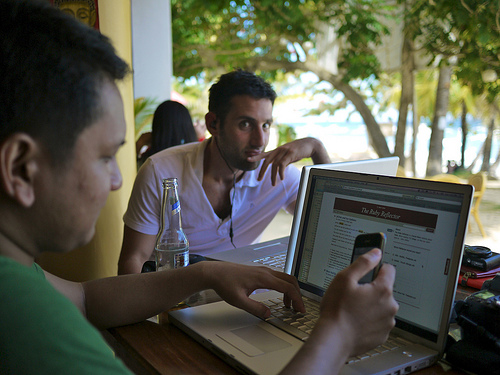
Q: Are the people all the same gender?
A: No, they are both male and female.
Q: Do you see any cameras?
A: Yes, there is a camera.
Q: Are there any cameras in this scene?
A: Yes, there is a camera.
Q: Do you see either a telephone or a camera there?
A: Yes, there is a camera.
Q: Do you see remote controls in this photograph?
A: No, there are no remote controls.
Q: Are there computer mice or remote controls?
A: No, there are no remote controls or computer mice.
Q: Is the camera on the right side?
A: Yes, the camera is on the right of the image.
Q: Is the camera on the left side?
A: No, the camera is on the right of the image.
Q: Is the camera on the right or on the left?
A: The camera is on the right of the image.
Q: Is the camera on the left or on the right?
A: The camera is on the right of the image.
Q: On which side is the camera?
A: The camera is on the right of the image.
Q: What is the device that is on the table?
A: The device is a camera.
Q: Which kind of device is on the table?
A: The device is a camera.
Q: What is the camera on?
A: The camera is on the table.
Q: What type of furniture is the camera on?
A: The camera is on the table.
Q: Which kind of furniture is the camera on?
A: The camera is on the table.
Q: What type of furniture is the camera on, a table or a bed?
A: The camera is on a table.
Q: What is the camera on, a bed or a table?
A: The camera is on a table.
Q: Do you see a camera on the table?
A: Yes, there is a camera on the table.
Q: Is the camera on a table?
A: Yes, the camera is on a table.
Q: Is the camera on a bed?
A: No, the camera is on a table.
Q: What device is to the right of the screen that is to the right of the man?
A: The device is a camera.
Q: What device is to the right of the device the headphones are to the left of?
A: The device is a camera.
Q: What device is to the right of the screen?
A: The device is a camera.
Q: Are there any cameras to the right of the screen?
A: Yes, there is a camera to the right of the screen.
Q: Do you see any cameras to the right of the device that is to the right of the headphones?
A: Yes, there is a camera to the right of the screen.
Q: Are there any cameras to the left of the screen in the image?
A: No, the camera is to the right of the screen.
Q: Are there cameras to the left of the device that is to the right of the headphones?
A: No, the camera is to the right of the screen.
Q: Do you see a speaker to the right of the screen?
A: No, there is a camera to the right of the screen.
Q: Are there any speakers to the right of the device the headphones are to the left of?
A: No, there is a camera to the right of the screen.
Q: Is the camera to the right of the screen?
A: Yes, the camera is to the right of the screen.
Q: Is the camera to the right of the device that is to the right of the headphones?
A: Yes, the camera is to the right of the screen.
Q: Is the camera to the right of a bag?
A: No, the camera is to the right of the screen.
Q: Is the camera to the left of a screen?
A: No, the camera is to the right of a screen.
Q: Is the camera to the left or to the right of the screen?
A: The camera is to the right of the screen.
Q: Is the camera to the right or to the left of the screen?
A: The camera is to the right of the screen.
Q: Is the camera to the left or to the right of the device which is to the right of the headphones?
A: The camera is to the right of the screen.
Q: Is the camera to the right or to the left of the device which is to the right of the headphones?
A: The camera is to the right of the screen.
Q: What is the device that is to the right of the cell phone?
A: The device is a camera.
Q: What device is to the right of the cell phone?
A: The device is a camera.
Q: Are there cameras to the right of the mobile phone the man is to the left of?
A: Yes, there is a camera to the right of the mobile phone.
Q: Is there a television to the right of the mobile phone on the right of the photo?
A: No, there is a camera to the right of the cell phone.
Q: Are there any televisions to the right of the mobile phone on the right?
A: No, there is a camera to the right of the cell phone.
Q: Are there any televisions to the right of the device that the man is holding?
A: No, there is a camera to the right of the cell phone.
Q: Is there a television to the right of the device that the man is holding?
A: No, there is a camera to the right of the cell phone.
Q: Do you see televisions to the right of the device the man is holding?
A: No, there is a camera to the right of the cell phone.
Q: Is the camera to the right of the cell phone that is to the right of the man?
A: Yes, the camera is to the right of the mobile phone.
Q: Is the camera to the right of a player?
A: No, the camera is to the right of the mobile phone.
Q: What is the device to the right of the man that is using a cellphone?
A: The device is a camera.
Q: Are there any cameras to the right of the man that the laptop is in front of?
A: Yes, there is a camera to the right of the man.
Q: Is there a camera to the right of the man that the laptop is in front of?
A: Yes, there is a camera to the right of the man.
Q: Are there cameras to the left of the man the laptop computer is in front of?
A: No, the camera is to the right of the man.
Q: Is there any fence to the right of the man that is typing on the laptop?
A: No, there is a camera to the right of the man.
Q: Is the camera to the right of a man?
A: Yes, the camera is to the right of a man.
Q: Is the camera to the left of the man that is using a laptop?
A: No, the camera is to the right of the man.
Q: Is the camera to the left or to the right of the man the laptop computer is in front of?
A: The camera is to the right of the man.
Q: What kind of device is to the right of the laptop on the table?
A: The device is a camera.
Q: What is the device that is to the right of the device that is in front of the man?
A: The device is a camera.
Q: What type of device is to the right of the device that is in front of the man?
A: The device is a camera.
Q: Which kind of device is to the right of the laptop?
A: The device is a camera.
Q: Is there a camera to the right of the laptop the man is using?
A: Yes, there is a camera to the right of the laptop computer.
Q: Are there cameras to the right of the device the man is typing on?
A: Yes, there is a camera to the right of the laptop computer.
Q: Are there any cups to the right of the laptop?
A: No, there is a camera to the right of the laptop.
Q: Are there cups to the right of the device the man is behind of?
A: No, there is a camera to the right of the laptop.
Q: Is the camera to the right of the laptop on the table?
A: Yes, the camera is to the right of the laptop.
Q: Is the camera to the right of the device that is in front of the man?
A: Yes, the camera is to the right of the laptop.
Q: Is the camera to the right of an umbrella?
A: No, the camera is to the right of the laptop.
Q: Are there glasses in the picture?
A: No, there are no glasses.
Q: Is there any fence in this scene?
A: No, there are no fences.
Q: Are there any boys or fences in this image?
A: No, there are no fences or boys.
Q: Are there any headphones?
A: Yes, there are headphones.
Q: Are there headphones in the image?
A: Yes, there are headphones.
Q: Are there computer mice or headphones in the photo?
A: Yes, there are headphones.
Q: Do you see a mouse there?
A: No, there are no computer mice.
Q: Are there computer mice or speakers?
A: No, there are no computer mice or speakers.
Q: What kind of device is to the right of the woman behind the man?
A: The device is headphones.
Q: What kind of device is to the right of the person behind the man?
A: The device is headphones.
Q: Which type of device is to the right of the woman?
A: The device is headphones.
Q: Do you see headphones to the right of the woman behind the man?
A: Yes, there are headphones to the right of the woman.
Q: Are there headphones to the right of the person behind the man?
A: Yes, there are headphones to the right of the woman.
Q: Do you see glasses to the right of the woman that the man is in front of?
A: No, there are headphones to the right of the woman.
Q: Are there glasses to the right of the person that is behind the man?
A: No, there are headphones to the right of the woman.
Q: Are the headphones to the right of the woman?
A: Yes, the headphones are to the right of the woman.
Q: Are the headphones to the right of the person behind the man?
A: Yes, the headphones are to the right of the woman.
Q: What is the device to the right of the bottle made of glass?
A: The device is headphones.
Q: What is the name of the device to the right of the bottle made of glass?
A: The device is headphones.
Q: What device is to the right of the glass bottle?
A: The device is headphones.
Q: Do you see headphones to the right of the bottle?
A: Yes, there are headphones to the right of the bottle.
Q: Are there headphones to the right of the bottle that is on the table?
A: Yes, there are headphones to the right of the bottle.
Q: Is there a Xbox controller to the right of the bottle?
A: No, there are headphones to the right of the bottle.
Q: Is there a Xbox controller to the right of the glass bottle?
A: No, there are headphones to the right of the bottle.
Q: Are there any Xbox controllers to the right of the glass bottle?
A: No, there are headphones to the right of the bottle.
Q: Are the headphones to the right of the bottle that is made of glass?
A: Yes, the headphones are to the right of the bottle.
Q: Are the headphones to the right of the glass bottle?
A: Yes, the headphones are to the right of the bottle.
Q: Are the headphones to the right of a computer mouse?
A: No, the headphones are to the right of the bottle.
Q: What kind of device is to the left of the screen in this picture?
A: The device is headphones.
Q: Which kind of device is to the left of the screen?
A: The device is headphones.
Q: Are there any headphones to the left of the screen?
A: Yes, there are headphones to the left of the screen.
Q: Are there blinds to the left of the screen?
A: No, there are headphones to the left of the screen.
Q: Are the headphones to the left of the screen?
A: Yes, the headphones are to the left of the screen.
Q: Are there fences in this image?
A: No, there are no fences.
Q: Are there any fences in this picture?
A: No, there are no fences.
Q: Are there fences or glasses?
A: No, there are no fences or glasses.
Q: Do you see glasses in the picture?
A: No, there are no glasses.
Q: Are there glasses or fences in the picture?
A: No, there are no glasses or fences.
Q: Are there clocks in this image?
A: No, there are no clocks.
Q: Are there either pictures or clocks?
A: No, there are no clocks or pictures.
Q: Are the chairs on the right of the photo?
A: Yes, the chairs are on the right of the image.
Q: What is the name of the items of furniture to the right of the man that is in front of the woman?
A: The pieces of furniture are chairs.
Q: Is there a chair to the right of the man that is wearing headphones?
A: Yes, there are chairs to the right of the man.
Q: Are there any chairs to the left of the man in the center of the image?
A: No, the chairs are to the right of the man.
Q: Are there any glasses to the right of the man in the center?
A: No, there are chairs to the right of the man.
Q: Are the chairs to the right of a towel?
A: No, the chairs are to the right of the man.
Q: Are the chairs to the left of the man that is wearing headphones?
A: No, the chairs are to the right of the man.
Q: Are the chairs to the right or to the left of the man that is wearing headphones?
A: The chairs are to the right of the man.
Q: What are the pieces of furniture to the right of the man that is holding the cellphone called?
A: The pieces of furniture are chairs.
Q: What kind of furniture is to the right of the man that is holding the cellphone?
A: The pieces of furniture are chairs.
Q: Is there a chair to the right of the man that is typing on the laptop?
A: Yes, there are chairs to the right of the man.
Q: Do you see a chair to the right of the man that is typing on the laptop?
A: Yes, there are chairs to the right of the man.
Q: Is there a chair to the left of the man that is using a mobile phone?
A: No, the chairs are to the right of the man.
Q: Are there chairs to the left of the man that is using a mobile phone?
A: No, the chairs are to the right of the man.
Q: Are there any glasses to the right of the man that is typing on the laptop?
A: No, there are chairs to the right of the man.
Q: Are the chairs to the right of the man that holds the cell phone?
A: Yes, the chairs are to the right of the man.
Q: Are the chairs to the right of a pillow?
A: No, the chairs are to the right of the man.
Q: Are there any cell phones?
A: Yes, there is a cell phone.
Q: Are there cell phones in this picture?
A: Yes, there is a cell phone.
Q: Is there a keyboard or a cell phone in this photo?
A: Yes, there is a cell phone.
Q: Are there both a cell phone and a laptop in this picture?
A: Yes, there are both a cell phone and a laptop.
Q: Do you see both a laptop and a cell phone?
A: Yes, there are both a cell phone and a laptop.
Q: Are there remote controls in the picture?
A: No, there are no remote controls.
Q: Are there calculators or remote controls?
A: No, there are no remote controls or calculators.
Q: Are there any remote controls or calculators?
A: No, there are no remote controls or calculators.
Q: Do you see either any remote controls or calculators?
A: No, there are no remote controls or calculators.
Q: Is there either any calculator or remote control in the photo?
A: No, there are no remote controls or calculators.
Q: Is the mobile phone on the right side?
A: Yes, the mobile phone is on the right of the image.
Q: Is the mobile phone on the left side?
A: No, the mobile phone is on the right of the image.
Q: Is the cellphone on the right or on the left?
A: The cellphone is on the right of the image.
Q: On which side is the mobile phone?
A: The mobile phone is on the right of the image.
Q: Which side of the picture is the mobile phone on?
A: The mobile phone is on the right of the image.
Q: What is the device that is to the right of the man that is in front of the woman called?
A: The device is a cell phone.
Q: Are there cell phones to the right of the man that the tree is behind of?
A: Yes, there is a cell phone to the right of the man.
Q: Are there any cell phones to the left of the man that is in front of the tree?
A: No, the cell phone is to the right of the man.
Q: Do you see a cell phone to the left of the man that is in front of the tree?
A: No, the cell phone is to the right of the man.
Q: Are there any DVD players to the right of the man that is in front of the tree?
A: No, there is a cell phone to the right of the man.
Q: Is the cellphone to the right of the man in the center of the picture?
A: Yes, the cellphone is to the right of the man.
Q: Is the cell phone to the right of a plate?
A: No, the cell phone is to the right of the man.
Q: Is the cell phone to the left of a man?
A: No, the cell phone is to the right of a man.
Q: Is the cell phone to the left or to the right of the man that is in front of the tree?
A: The cell phone is to the right of the man.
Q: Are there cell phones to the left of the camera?
A: Yes, there is a cell phone to the left of the camera.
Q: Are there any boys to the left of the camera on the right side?
A: No, there is a cell phone to the left of the camera.